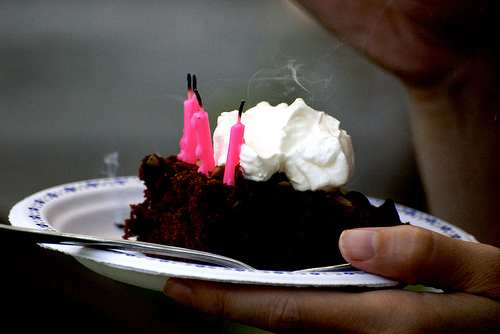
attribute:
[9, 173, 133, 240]
plate — white, blue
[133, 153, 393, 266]
chocolate cake — slice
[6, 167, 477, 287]
plate — White, blue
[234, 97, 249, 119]
string — burnt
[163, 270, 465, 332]
finger — index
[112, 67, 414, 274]
cake — chocolate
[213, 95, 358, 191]
whipped cream — fluffy, White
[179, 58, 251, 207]
candles — pink